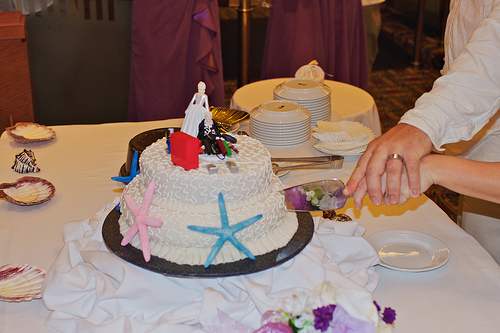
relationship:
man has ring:
[344, 85, 452, 210] [388, 148, 411, 168]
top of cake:
[178, 56, 234, 169] [111, 115, 290, 265]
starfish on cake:
[191, 183, 264, 279] [111, 115, 290, 265]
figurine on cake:
[178, 56, 234, 169] [111, 115, 290, 265]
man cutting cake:
[340, 0, 499, 206] [111, 115, 290, 265]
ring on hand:
[388, 148, 411, 168] [344, 85, 452, 210]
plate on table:
[296, 81, 335, 99] [44, 114, 133, 224]